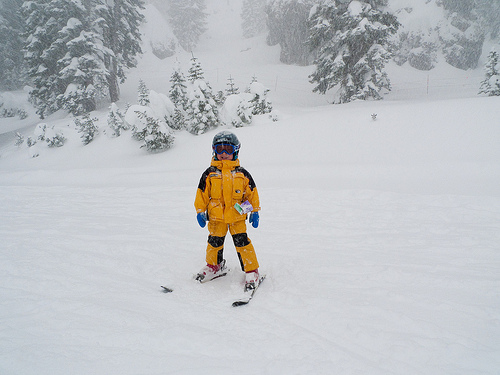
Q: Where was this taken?
A: Ski slope.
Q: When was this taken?
A: Winter.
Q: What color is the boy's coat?
A: Yellow.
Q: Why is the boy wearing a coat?
A: Cold.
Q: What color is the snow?
A: White.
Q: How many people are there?
A: 1.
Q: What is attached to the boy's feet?
A: Skis.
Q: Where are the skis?
A: On the boy's feet.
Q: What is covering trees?
A: Snow.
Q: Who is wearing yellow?
A: A boy.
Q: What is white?
A: Snow.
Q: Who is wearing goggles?
A: The boy.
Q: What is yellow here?
A: Kids snow suit.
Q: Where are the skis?
A: Kids feet.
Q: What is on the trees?
A: Snow.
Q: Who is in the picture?
A: A boy.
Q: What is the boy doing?
A: Skiing.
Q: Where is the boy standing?
A: The snow.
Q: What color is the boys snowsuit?
A: Yellow.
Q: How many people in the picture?
A: One.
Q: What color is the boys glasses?
A: Blue.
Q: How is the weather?
A: Cold and snowy.